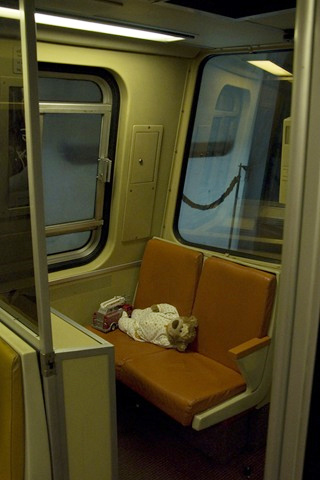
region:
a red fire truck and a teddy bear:
[88, 290, 198, 352]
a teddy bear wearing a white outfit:
[116, 297, 198, 354]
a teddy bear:
[116, 294, 200, 354]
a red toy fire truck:
[93, 294, 135, 332]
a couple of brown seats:
[74, 231, 281, 434]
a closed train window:
[0, 58, 129, 289]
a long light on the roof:
[0, 3, 193, 48]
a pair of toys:
[88, 288, 200, 352]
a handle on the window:
[94, 155, 114, 184]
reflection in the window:
[180, 45, 292, 263]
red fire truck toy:
[100, 297, 126, 339]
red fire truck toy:
[93, 303, 137, 334]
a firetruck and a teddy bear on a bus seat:
[80, 238, 275, 436]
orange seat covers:
[99, 231, 276, 412]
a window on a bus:
[27, 65, 127, 309]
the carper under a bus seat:
[120, 273, 273, 478]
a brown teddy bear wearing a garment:
[120, 300, 204, 361]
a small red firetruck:
[84, 290, 142, 338]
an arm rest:
[219, 313, 274, 386]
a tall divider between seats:
[1, 1, 77, 440]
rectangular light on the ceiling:
[1, 0, 209, 57]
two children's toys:
[80, 281, 204, 384]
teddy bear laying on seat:
[120, 298, 194, 357]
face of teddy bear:
[162, 314, 194, 350]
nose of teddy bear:
[168, 317, 179, 329]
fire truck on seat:
[94, 292, 131, 336]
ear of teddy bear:
[174, 342, 189, 350]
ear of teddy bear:
[178, 309, 200, 325]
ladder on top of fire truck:
[98, 293, 126, 311]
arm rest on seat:
[230, 336, 265, 389]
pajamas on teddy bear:
[128, 306, 166, 343]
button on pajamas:
[151, 320, 157, 328]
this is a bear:
[111, 301, 197, 354]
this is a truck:
[89, 289, 144, 336]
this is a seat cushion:
[78, 300, 241, 424]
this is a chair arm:
[199, 333, 280, 431]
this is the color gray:
[63, 347, 69, 352]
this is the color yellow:
[80, 412, 96, 421]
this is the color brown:
[15, 405, 19, 412]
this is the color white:
[147, 325, 153, 332]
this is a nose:
[171, 315, 181, 330]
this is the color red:
[107, 316, 110, 322]